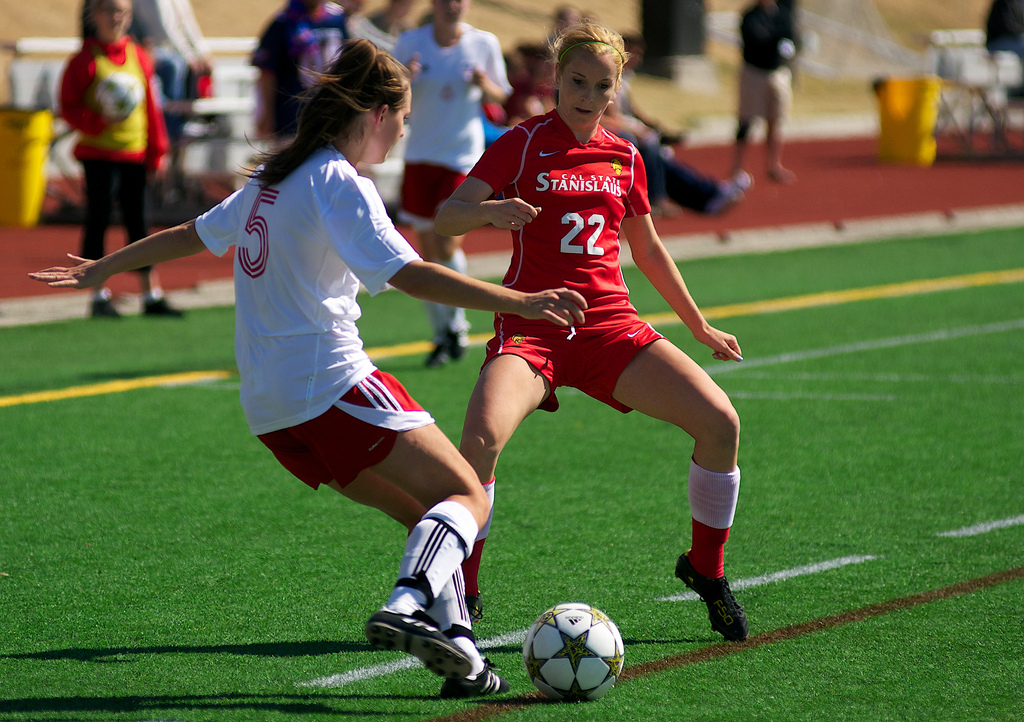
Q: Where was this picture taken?
A: Soccer field.